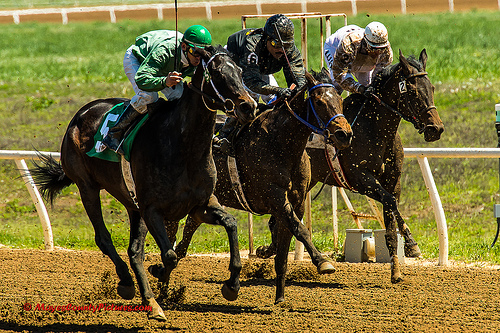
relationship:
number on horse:
[87, 110, 130, 158] [34, 40, 261, 313]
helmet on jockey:
[177, 24, 213, 50] [100, 23, 214, 157]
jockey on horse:
[100, 23, 214, 157] [34, 40, 261, 313]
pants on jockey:
[124, 49, 186, 114] [209, 14, 308, 153]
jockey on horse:
[209, 14, 308, 153] [214, 67, 354, 304]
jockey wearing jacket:
[209, 14, 308, 153] [225, 30, 307, 92]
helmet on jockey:
[177, 24, 212, 44] [99, 23, 212, 158]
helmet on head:
[261, 10, 296, 45] [259, 12, 296, 62]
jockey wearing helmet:
[209, 15, 309, 154] [261, 10, 296, 45]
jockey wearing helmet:
[317, 9, 398, 95] [363, 17, 392, 51]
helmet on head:
[363, 17, 392, 51] [356, 17, 398, 64]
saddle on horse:
[89, 105, 146, 162] [69, 62, 254, 313]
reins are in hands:
[187, 79, 224, 106] [164, 65, 183, 86]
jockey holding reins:
[101, 14, 214, 164] [187, 79, 224, 106]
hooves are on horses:
[102, 238, 421, 328] [10, 38, 454, 326]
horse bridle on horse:
[306, 99, 328, 123] [288, 79, 363, 160]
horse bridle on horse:
[295, 89, 337, 132] [220, 72, 334, 308]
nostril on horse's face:
[339, 131, 346, 138] [308, 63, 358, 151]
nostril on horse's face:
[352, 133, 354, 143] [308, 63, 358, 151]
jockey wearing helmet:
[100, 23, 214, 157] [180, 23, 212, 52]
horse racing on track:
[34, 40, 261, 313] [1, 245, 498, 331]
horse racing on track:
[201, 69, 353, 308] [1, 2, 498, 329]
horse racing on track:
[253, 48, 443, 285] [1, 245, 498, 331]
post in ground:
[1, 2, 58, 26] [322, 274, 442, 309]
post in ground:
[420, 144, 461, 269] [3, 246, 498, 331]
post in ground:
[8, 149, 58, 249] [3, 246, 498, 331]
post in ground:
[131, 4, 193, 27] [0, 4, 457, 31]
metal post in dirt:
[328, 179, 339, 259] [1, 245, 498, 331]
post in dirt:
[416, 156, 448, 267] [1, 245, 498, 331]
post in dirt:
[296, 11, 311, 72] [0, 0, 498, 330]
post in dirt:
[96, 12, 141, 28] [0, 0, 498, 330]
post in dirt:
[198, 3, 216, 15] [23, 256, 460, 321]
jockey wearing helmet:
[100, 23, 214, 157] [181, 21, 211, 45]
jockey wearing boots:
[100, 23, 214, 157] [95, 94, 138, 172]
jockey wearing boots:
[100, 23, 214, 157] [85, 124, 115, 167]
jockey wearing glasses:
[100, 23, 214, 157] [181, 43, 206, 57]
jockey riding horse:
[209, 14, 308, 153] [96, 72, 354, 322]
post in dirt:
[322, 146, 353, 257] [281, 247, 430, 313]